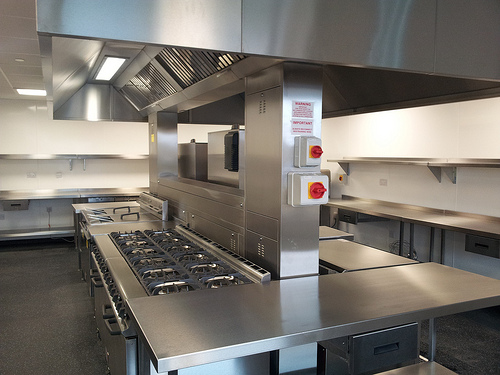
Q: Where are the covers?
A: On ovens.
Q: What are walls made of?
A: Steel.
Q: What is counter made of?
A: Steel.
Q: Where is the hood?
A: Over ovens.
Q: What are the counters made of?
A: Stainless steel.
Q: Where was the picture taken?
A: In a kitchen.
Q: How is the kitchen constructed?
A: Stainless steel.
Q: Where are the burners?
A: On the stove top?.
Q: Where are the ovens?
A: Under the burners.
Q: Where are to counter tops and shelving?
A: Along the walls.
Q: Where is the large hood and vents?
A: Over the stoves.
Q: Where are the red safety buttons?
A: On the support column.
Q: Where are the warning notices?
A: Above the safety buttons.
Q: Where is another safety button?
A: On the wall.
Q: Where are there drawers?
A: Under the counter tops.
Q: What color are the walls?
A: White.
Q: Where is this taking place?
A: In a kitchen.